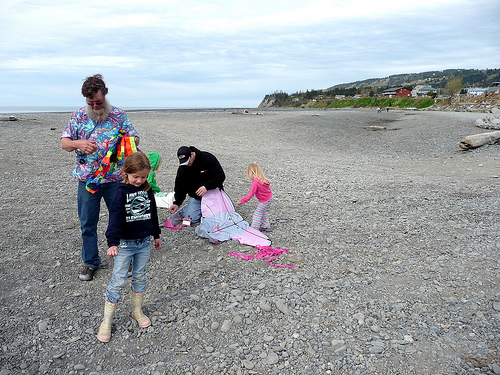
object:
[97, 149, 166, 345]
girl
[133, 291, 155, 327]
boots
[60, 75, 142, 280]
man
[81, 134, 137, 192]
kite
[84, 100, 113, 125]
beard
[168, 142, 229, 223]
man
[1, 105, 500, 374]
ground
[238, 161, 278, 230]
girl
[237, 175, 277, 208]
pink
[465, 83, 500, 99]
houses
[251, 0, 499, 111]
back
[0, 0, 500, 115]
sky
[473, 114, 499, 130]
logs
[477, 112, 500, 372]
side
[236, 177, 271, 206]
shirt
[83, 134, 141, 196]
towel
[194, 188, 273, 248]
kite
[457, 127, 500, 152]
piece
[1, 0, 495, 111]
background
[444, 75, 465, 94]
tree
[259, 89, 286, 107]
slope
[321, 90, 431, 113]
patch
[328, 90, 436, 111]
grass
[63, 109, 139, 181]
shirt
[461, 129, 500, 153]
log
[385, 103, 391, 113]
person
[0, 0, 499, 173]
distance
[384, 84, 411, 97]
building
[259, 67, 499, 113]
hill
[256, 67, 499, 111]
cliff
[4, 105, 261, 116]
ocean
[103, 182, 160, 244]
shirt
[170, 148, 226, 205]
shirt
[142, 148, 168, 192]
child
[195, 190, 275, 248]
elephant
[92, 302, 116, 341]
boot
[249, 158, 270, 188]
hair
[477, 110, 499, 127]
driftwood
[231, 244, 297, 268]
tassels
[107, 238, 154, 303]
jeans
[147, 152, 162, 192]
sweatshirt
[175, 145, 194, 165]
basball hat